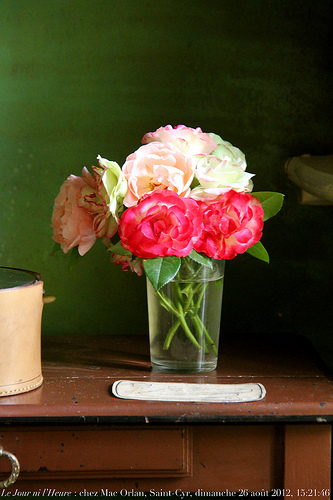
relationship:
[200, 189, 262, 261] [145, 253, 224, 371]
flower in cup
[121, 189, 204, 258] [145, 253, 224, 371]
flower in cup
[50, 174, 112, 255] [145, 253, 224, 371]
flower in cup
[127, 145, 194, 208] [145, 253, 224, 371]
flower in cup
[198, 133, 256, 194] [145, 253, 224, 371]
flower in cup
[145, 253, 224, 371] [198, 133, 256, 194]
cup holding flower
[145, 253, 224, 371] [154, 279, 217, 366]
cup holding water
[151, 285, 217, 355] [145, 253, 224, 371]
stems in vase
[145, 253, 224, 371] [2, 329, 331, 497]
cup on top of desk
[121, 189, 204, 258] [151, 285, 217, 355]
flower has stems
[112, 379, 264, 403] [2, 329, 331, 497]
dish on top of desk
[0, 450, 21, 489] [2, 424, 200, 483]
handle on front of drawer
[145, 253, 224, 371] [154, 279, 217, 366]
cup has water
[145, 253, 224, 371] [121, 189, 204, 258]
cup has flower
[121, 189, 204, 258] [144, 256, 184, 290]
flower has leaf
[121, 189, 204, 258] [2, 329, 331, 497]
flower on table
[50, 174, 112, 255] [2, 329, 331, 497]
flower on desk